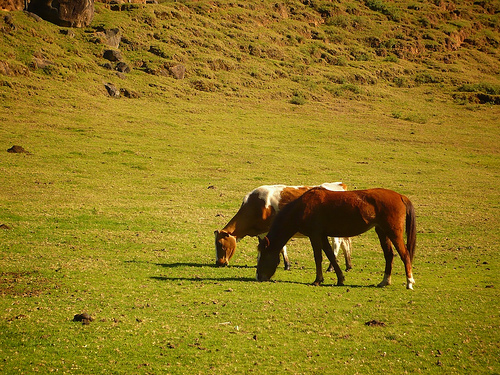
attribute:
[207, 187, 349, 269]
cow — brown, white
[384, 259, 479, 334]
hoof — white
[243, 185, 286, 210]
white spot — large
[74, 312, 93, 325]
dirt — clumped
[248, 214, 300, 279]
face — brown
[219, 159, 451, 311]
horse — brown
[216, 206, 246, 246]
neck — brown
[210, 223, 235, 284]
face — brown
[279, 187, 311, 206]
spot — brown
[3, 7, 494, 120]
hillside — grass covered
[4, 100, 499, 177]
grass — short, green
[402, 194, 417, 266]
hair — brown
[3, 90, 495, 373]
field — grass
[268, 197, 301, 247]
neck — brown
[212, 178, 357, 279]
cow — white, brown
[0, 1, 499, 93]
outcropping — rocky